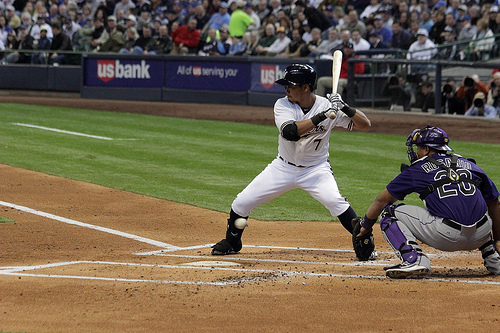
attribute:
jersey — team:
[268, 92, 341, 169]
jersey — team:
[379, 155, 499, 222]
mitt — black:
[351, 217, 374, 259]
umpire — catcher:
[338, 97, 499, 309]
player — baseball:
[211, 43, 368, 272]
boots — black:
[194, 200, 383, 275]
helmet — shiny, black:
[273, 61, 319, 89]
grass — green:
[161, 130, 247, 192]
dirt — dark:
[251, 268, 278, 283]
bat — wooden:
[328, 49, 342, 121]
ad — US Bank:
[97, 53, 155, 82]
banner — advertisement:
[78, 56, 253, 91]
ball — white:
[234, 213, 251, 230]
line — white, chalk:
[1, 198, 186, 255]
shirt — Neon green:
[223, 10, 252, 37]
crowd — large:
[0, 5, 499, 62]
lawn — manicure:
[2, 100, 497, 245]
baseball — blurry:
[233, 217, 249, 232]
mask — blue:
[403, 129, 417, 159]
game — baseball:
[0, 31, 492, 327]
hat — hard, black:
[266, 46, 333, 120]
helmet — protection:
[399, 123, 450, 167]